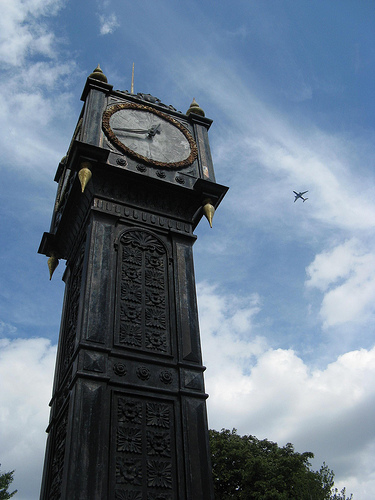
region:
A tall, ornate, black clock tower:
[37, 59, 215, 498]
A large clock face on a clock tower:
[101, 100, 197, 171]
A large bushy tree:
[206, 428, 323, 499]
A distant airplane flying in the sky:
[290, 188, 309, 203]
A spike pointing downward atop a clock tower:
[75, 167, 91, 192]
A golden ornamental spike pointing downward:
[201, 203, 214, 226]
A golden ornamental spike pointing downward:
[47, 255, 58, 280]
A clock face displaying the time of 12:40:
[102, 101, 196, 169]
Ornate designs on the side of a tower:
[106, 223, 177, 498]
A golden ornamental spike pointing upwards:
[88, 62, 108, 81]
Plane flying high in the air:
[288, 182, 309, 205]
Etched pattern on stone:
[109, 390, 186, 495]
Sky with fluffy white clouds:
[248, 234, 368, 380]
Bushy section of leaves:
[214, 421, 337, 499]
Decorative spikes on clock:
[71, 165, 96, 201]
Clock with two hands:
[100, 93, 207, 185]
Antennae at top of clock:
[101, 31, 158, 97]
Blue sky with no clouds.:
[298, 9, 347, 56]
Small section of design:
[108, 219, 184, 370]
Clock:
[99, 92, 200, 176]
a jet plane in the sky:
[288, 188, 323, 211]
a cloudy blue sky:
[1, 2, 371, 497]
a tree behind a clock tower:
[206, 424, 342, 498]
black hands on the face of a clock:
[115, 119, 163, 134]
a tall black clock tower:
[39, 62, 230, 497]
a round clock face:
[102, 96, 202, 165]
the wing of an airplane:
[300, 187, 308, 194]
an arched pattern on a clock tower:
[106, 221, 177, 357]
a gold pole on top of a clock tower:
[126, 55, 138, 92]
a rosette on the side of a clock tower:
[110, 359, 130, 374]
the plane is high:
[290, 187, 311, 207]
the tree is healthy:
[215, 426, 340, 497]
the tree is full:
[220, 431, 329, 497]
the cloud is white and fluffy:
[248, 359, 355, 438]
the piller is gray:
[73, 240, 203, 491]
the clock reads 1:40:
[104, 95, 199, 174]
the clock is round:
[104, 93, 202, 173]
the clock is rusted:
[103, 100, 116, 154]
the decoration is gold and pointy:
[199, 201, 220, 227]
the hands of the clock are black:
[113, 124, 164, 137]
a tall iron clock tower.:
[35, 64, 231, 498]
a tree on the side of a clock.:
[210, 424, 355, 498]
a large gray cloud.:
[0, 319, 61, 497]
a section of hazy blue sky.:
[21, 214, 34, 274]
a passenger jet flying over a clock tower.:
[290, 182, 315, 220]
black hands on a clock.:
[110, 116, 164, 146]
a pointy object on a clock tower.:
[201, 199, 218, 231]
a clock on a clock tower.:
[95, 104, 194, 168]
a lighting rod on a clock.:
[127, 58, 146, 93]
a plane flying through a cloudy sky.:
[279, 149, 318, 237]